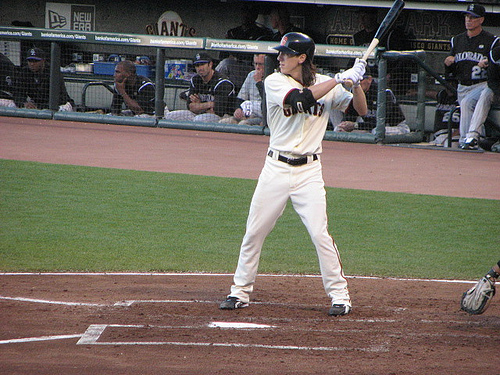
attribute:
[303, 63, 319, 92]
hair — long, brown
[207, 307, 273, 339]
home plate — white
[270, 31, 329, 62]
helmet — blue, hard, black, red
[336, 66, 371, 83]
gloves — white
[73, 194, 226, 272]
turf — green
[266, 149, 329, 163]
belt — black, leather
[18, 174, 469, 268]
grass — green, lawn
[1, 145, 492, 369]
field — part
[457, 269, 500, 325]
glove — part, black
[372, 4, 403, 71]
bat — wooden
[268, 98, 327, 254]
uniform — black, white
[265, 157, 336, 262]
trouser — uniform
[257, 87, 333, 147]
jersey — white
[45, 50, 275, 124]
fence — part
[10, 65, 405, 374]
game — baseball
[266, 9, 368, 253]
player — hitting, batting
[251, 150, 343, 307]
pants — white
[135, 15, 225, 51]
giants — logo, red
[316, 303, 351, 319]
cleat — black